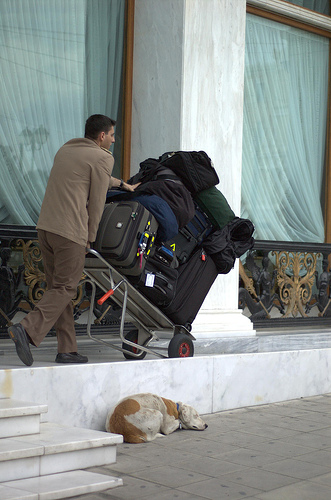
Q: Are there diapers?
A: No, there are no diapers.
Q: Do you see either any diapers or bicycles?
A: No, there are no diapers or bicycles.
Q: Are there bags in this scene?
A: Yes, there is a bag.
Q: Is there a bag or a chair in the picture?
A: Yes, there is a bag.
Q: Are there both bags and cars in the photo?
A: No, there is a bag but no cars.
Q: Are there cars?
A: No, there are no cars.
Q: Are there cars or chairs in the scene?
A: No, there are no cars or chairs.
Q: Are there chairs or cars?
A: No, there are no cars or chairs.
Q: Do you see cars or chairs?
A: No, there are no cars or chairs.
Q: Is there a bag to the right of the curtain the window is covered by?
A: Yes, there is a bag to the right of the curtain.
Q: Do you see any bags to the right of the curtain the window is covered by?
A: Yes, there is a bag to the right of the curtain.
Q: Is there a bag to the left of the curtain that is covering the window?
A: No, the bag is to the right of the curtain.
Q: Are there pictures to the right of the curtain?
A: No, there is a bag to the right of the curtain.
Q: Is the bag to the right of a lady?
A: No, the bag is to the right of a curtain.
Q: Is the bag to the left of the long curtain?
A: No, the bag is to the right of the curtain.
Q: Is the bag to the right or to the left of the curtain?
A: The bag is to the right of the curtain.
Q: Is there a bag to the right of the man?
A: Yes, there is a bag to the right of the man.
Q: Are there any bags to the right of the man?
A: Yes, there is a bag to the right of the man.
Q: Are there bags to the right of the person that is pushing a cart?
A: Yes, there is a bag to the right of the man.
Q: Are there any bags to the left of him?
A: No, the bag is to the right of the man.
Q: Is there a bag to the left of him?
A: No, the bag is to the right of the man.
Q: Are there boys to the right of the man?
A: No, there is a bag to the right of the man.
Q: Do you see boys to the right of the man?
A: No, there is a bag to the right of the man.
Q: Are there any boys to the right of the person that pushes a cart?
A: No, there is a bag to the right of the man.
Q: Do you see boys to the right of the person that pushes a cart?
A: No, there is a bag to the right of the man.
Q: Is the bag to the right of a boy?
A: No, the bag is to the right of a man.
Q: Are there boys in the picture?
A: No, there are no boys.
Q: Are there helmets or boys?
A: No, there are no boys or helmets.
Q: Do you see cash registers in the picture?
A: No, there are no cash registers.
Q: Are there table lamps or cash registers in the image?
A: No, there are no cash registers or table lamps.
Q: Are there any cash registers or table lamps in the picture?
A: No, there are no cash registers or table lamps.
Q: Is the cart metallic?
A: Yes, the cart is metallic.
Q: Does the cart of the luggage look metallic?
A: Yes, the cart is metallic.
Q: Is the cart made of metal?
A: Yes, the cart is made of metal.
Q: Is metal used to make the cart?
A: Yes, the cart is made of metal.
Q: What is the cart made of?
A: The cart is made of metal.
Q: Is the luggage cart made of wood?
A: No, the cart is made of metal.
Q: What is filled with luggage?
A: The cart is filled with luggage.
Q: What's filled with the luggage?
A: The cart is filled with luggage.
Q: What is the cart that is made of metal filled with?
A: The cart is filled with luggage.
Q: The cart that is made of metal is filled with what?
A: The cart is filled with luggage.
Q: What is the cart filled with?
A: The cart is filled with luggage.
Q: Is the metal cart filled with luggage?
A: Yes, the cart is filled with luggage.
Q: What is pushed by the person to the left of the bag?
A: The cart is pushed by the man.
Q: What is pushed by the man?
A: The cart is pushed by the man.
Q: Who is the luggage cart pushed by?
A: The cart is pushed by the man.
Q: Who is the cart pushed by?
A: The cart is pushed by the man.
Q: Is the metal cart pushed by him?
A: Yes, the cart is pushed by the man.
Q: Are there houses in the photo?
A: No, there are no houses.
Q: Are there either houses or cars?
A: No, there are no houses or cars.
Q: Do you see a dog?
A: Yes, there is a dog.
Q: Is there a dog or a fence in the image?
A: Yes, there is a dog.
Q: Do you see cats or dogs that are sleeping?
A: Yes, the dog is sleeping.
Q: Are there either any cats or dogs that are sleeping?
A: Yes, the dog is sleeping.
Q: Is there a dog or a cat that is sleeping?
A: Yes, the dog is sleeping.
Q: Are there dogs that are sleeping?
A: Yes, there is a dog that is sleeping.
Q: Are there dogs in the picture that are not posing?
A: Yes, there is a dog that is sleeping.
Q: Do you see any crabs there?
A: No, there are no crabs.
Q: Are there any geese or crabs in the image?
A: No, there are no crabs or geese.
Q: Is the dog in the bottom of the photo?
A: Yes, the dog is in the bottom of the image.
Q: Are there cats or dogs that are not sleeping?
A: No, there is a dog but it is sleeping.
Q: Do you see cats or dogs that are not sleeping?
A: No, there is a dog but it is sleeping.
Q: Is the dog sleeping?
A: Yes, the dog is sleeping.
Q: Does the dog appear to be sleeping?
A: Yes, the dog is sleeping.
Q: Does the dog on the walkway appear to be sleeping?
A: Yes, the dog is sleeping.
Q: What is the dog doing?
A: The dog is sleeping.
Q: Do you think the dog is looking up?
A: No, the dog is sleeping.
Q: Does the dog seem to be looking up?
A: No, the dog is sleeping.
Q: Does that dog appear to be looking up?
A: No, the dog is sleeping.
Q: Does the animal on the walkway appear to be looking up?
A: No, the dog is sleeping.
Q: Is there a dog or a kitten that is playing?
A: No, there is a dog but it is sleeping.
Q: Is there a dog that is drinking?
A: No, there is a dog but it is sleeping.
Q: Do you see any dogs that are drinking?
A: No, there is a dog but it is sleeping.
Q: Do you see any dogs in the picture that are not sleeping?
A: No, there is a dog but it is sleeping.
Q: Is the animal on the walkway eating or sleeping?
A: The dog is sleeping.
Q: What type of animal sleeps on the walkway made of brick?
A: The animal is a dog.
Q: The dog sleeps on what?
A: The dog sleeps on the walkway.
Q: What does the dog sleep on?
A: The dog sleeps on the walkway.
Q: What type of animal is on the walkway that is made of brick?
A: The animal is a dog.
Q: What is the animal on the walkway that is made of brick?
A: The animal is a dog.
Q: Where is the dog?
A: The dog is on the walkway.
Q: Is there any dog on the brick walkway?
A: Yes, there is a dog on the walkway.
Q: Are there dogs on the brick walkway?
A: Yes, there is a dog on the walkway.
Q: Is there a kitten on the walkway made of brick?
A: No, there is a dog on the walkway.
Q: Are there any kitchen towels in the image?
A: No, there are no kitchen towels.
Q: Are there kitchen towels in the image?
A: No, there are no kitchen towels.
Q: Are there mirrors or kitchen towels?
A: No, there are no kitchen towels or mirrors.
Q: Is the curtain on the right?
A: No, the curtain is on the left of the image.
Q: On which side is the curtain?
A: The curtain is on the left of the image.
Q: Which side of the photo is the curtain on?
A: The curtain is on the left of the image.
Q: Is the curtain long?
A: Yes, the curtain is long.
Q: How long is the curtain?
A: The curtain is long.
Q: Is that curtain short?
A: No, the curtain is long.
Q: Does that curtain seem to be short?
A: No, the curtain is long.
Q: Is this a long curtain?
A: Yes, this is a long curtain.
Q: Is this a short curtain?
A: No, this is a long curtain.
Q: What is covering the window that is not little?
A: The curtain is covering the window.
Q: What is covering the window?
A: The curtain is covering the window.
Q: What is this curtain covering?
A: The curtain is covering the window.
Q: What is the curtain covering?
A: The curtain is covering the window.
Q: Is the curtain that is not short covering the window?
A: Yes, the curtain is covering the window.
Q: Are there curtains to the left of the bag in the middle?
A: Yes, there is a curtain to the left of the bag.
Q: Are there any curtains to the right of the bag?
A: No, the curtain is to the left of the bag.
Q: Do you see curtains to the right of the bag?
A: No, the curtain is to the left of the bag.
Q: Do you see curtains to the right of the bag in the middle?
A: No, the curtain is to the left of the bag.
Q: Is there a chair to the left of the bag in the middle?
A: No, there is a curtain to the left of the bag.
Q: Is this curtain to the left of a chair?
A: No, the curtain is to the left of a bag.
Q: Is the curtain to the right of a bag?
A: No, the curtain is to the left of a bag.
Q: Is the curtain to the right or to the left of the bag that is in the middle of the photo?
A: The curtain is to the left of the bag.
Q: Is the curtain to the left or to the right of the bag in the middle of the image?
A: The curtain is to the left of the bag.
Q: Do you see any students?
A: No, there are no students.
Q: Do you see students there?
A: No, there are no students.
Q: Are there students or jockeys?
A: No, there are no students or jockeys.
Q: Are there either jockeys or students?
A: No, there are no students or jockeys.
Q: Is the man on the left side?
A: Yes, the man is on the left of the image.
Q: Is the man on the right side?
A: No, the man is on the left of the image.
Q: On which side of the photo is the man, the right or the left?
A: The man is on the left of the image.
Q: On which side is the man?
A: The man is on the left of the image.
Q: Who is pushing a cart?
A: The man is pushing a cart.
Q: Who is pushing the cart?
A: The man is pushing a cart.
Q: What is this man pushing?
A: The man is pushing a cart.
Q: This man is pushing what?
A: The man is pushing a cart.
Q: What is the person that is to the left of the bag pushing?
A: The man is pushing a cart.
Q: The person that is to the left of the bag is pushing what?
A: The man is pushing a cart.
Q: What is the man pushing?
A: The man is pushing a cart.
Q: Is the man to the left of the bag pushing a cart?
A: Yes, the man is pushing a cart.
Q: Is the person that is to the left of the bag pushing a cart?
A: Yes, the man is pushing a cart.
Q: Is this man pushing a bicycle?
A: No, the man is pushing a cart.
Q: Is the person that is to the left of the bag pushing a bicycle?
A: No, the man is pushing a cart.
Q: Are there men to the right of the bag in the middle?
A: No, the man is to the left of the bag.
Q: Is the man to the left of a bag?
A: Yes, the man is to the left of a bag.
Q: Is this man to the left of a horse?
A: No, the man is to the left of a bag.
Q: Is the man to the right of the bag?
A: No, the man is to the left of the bag.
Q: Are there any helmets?
A: No, there are no helmets.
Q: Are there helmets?
A: No, there are no helmets.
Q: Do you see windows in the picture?
A: Yes, there is a window.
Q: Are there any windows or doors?
A: Yes, there is a window.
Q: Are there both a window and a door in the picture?
A: No, there is a window but no doors.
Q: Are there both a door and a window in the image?
A: No, there is a window but no doors.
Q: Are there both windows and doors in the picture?
A: No, there is a window but no doors.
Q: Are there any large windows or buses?
A: Yes, there is a large window.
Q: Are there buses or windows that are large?
A: Yes, the window is large.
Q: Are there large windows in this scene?
A: Yes, there is a large window.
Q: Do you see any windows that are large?
A: Yes, there is a window that is large.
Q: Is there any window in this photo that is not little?
A: Yes, there is a large window.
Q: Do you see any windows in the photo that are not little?
A: Yes, there is a large window.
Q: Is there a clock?
A: No, there are no clocks.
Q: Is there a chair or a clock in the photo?
A: No, there are no clocks or chairs.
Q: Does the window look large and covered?
A: Yes, the window is large and covered.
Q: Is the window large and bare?
A: No, the window is large but covered.